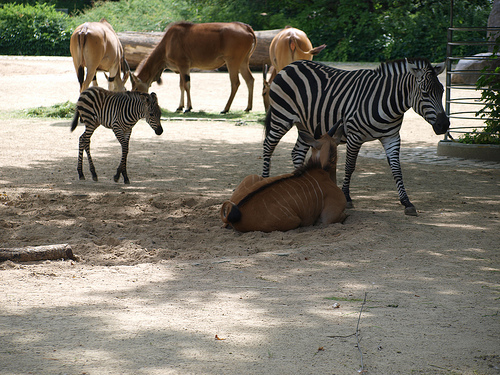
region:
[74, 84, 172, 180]
Baby zebra walking on dirt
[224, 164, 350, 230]
Brown animal on ground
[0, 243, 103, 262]
Piece of wood on ground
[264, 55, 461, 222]
Adult zebra walking on dirt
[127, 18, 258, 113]
Brown animal grazing on hay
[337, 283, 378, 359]
Gray twig sticking out of ground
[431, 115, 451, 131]
Black nose on zebra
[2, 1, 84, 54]
Bush green plant behind animals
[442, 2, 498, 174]
Gray metal fence poles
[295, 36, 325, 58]
Swishing brown tail with tufted hair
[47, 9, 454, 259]
a group of animals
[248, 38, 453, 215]
the zebra is black and white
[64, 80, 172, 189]
a baby zebra walking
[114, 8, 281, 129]
a brown horse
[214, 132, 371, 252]
the animal is laying down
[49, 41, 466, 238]
the baby zebra is following the big zebra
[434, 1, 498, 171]
the fence in metal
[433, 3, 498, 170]
a green bush inside the metal fence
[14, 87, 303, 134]
a patch of grass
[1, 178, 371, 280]
a shallow hole in the ground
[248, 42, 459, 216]
large zebra walking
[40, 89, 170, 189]
black and white baby zebra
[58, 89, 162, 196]
black and white baby zebra walking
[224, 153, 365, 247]
gazelle laying on ground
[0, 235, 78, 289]
small tree long on ground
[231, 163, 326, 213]
long black mane on animal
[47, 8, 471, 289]
group of animals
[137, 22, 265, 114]
brown horse standing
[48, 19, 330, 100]
group of horse grazing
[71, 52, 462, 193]
baby zebra following large zebra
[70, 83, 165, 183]
a black and white zebra walking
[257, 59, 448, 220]
a black and white zebra walking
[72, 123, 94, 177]
a black and white zebra leg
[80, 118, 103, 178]
a black and white zebra leg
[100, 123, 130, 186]
a black and white zebra leg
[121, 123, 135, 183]
a black and white zebra leg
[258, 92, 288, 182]
a black and white zebra leg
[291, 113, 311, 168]
a black and white zebra leg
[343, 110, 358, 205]
a black and white zebra leg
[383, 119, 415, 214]
a black and white zebra leg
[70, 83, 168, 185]
baby zebra is walking on the ground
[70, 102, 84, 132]
black tail on zebra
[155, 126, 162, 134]
black nose on zebra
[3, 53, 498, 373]
ground under zebra is sandy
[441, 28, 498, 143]
metal fence to the right of the big zebra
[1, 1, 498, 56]
green bushes behind zebras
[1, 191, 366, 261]
sand pit on ground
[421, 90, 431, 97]
black eye on zebra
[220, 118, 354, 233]
animal sitting next to zebra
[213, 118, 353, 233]
animal sitting in sand pit